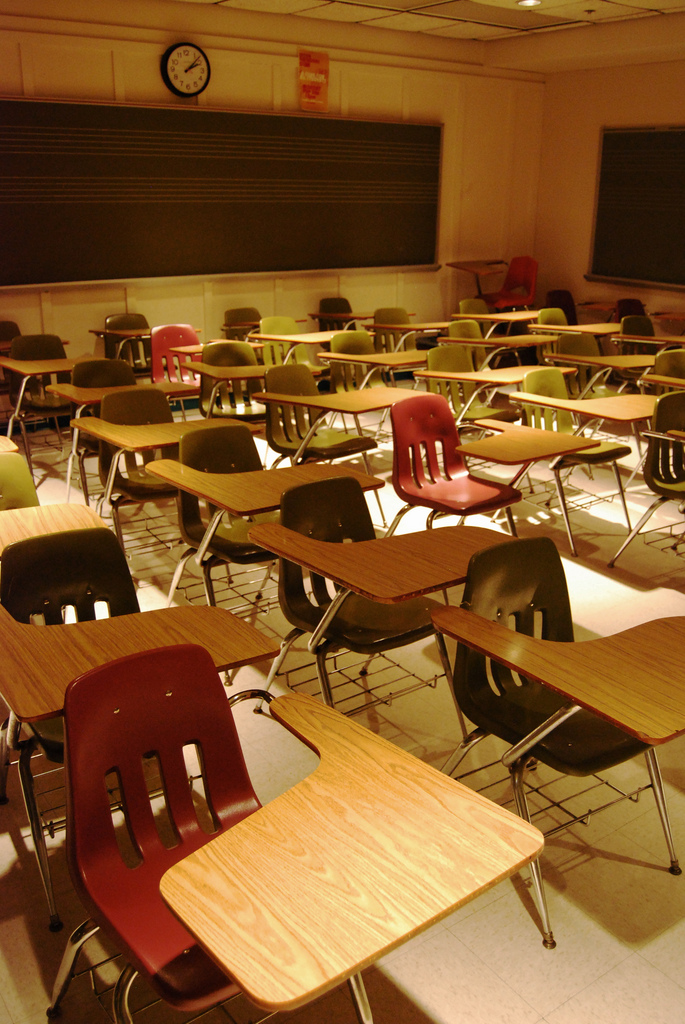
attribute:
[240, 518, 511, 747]
desk — empty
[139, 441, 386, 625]
desk — empty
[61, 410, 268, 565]
desk — empty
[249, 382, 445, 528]
desk — empty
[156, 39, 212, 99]
clock — white colored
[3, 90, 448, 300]
chalkboard — black colored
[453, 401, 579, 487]
desk — red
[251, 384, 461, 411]
desk — red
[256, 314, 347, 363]
desk — red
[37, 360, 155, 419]
desk — red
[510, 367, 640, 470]
desk — green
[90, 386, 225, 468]
desk — green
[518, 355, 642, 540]
desk — green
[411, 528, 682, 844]
desk — green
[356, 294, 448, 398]
desk — green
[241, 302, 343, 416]
desk — green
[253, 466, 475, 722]
desk — green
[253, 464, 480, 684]
desk — green